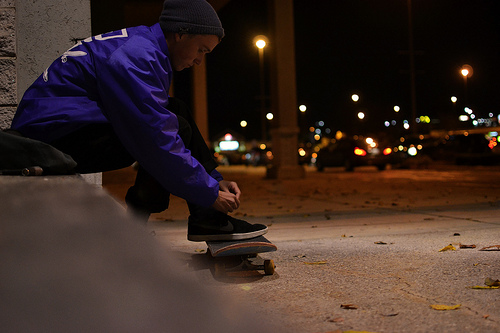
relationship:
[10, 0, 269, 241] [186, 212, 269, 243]
man tying shoe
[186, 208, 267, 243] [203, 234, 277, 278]
foot on top of skateboard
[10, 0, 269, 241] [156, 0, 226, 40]
man wearing hat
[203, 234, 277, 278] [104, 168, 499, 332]
skateboard on top of sidewalk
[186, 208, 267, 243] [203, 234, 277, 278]
foot resting on skateboard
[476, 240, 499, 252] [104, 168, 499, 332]
leaf sitting on sidewalk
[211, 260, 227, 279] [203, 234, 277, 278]
wheel mounted on skateboard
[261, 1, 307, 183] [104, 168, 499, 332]
pillar on top of sidewalk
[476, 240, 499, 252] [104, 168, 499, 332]
leaf on top of sidewalk